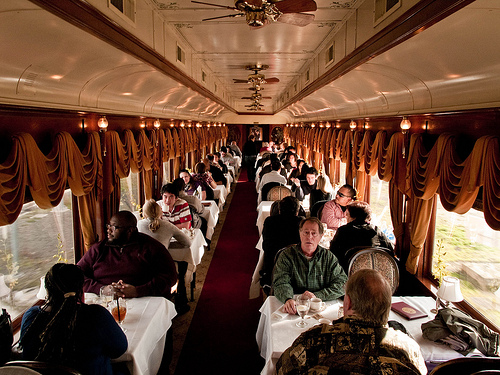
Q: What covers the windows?
A: Curtains.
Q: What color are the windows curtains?
A: Orange.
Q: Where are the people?
A: On the train.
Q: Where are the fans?
A: On the ceiling.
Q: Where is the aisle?
A: Between the tables.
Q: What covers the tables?
A: Tablecloths.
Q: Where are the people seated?
A: At tables.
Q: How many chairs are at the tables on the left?
A: Two.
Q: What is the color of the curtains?
A: Brown.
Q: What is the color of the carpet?
A: Red.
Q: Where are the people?
A: In the train.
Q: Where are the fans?
A: On the ceiling.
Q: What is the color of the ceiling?
A: Beige.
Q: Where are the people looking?
A: Outside the window.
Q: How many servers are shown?
A: One.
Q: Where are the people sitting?
A: In a train.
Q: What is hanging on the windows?
A: Curtains.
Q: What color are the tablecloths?
A: White.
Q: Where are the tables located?
A: Next to the windows.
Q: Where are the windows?
A: On either side of the tables.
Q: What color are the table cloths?
A: White.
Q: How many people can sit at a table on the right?
A: 2.